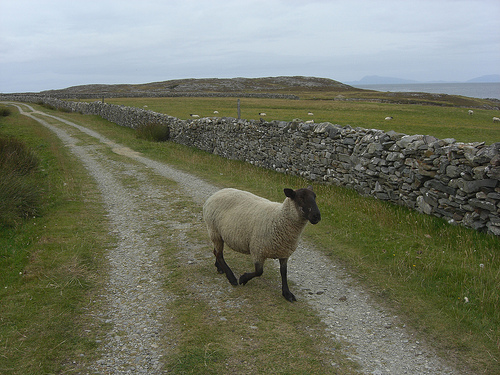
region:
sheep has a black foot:
[248, 260, 266, 295]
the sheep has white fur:
[212, 191, 272, 237]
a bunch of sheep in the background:
[180, 95, 499, 133]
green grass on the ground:
[36, 230, 82, 331]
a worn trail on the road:
[46, 130, 164, 183]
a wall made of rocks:
[285, 120, 496, 163]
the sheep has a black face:
[286, 186, 333, 236]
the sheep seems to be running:
[183, 166, 346, 322]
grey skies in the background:
[50, 6, 491, 61]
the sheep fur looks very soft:
[212, 195, 313, 271]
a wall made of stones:
[23, 88, 499, 233]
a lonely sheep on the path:
[178, 163, 329, 306]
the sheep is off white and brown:
[176, 180, 342, 315]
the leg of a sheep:
[275, 255, 305, 300]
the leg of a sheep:
[240, 260, 260, 290]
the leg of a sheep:
[210, 242, 237, 292]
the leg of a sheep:
[206, 241, 220, 273]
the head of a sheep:
[283, 183, 338, 228]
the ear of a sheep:
[278, 181, 296, 198]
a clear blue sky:
[1, 0, 498, 99]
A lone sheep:
[202, 175, 315, 297]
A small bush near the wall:
[117, 119, 184, 156]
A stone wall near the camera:
[118, 95, 483, 222]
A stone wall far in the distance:
[72, 91, 430, 102]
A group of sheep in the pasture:
[139, 98, 499, 130]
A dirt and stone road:
[40, 111, 327, 358]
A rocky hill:
[0, 75, 365, 91]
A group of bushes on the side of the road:
[5, 135, 35, 244]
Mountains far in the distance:
[355, 67, 413, 89]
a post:
[226, 95, 257, 139]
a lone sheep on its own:
[167, 137, 419, 324]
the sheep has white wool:
[151, 145, 356, 320]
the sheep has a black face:
[131, 126, 397, 333]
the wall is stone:
[332, 106, 429, 217]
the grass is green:
[38, 152, 133, 195]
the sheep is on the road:
[56, 142, 405, 344]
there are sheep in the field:
[180, 92, 437, 219]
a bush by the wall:
[108, 106, 202, 176]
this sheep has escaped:
[142, 140, 416, 339]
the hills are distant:
[199, 61, 466, 318]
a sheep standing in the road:
[161, 174, 343, 304]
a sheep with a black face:
[253, 177, 339, 240]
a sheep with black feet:
[166, 183, 337, 323]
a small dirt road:
[31, 98, 203, 330]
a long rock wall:
[165, 101, 479, 172]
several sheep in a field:
[151, 98, 487, 132]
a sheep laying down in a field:
[381, 107, 395, 127]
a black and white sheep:
[173, 167, 335, 291]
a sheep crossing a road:
[41, 149, 396, 370]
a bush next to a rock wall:
[111, 116, 188, 152]